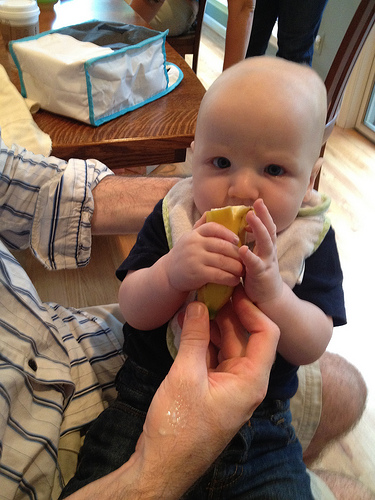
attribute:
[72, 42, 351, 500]
child — boy, bald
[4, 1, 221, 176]
table — here, wooden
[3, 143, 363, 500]
man — adult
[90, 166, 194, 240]
arm — hairy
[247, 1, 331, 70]
pants — blue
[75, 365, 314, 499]
jeans — blue, dark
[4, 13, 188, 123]
bag — white, blue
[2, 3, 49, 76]
cup — plastic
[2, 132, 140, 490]
shirt — striped, blue, white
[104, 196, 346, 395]
shirt — blue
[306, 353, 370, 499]
legs — hairy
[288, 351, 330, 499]
shorts — tan